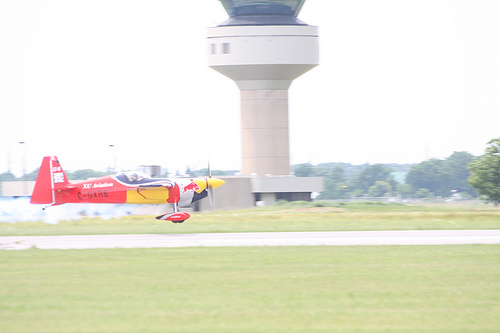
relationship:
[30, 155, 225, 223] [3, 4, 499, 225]
plane in air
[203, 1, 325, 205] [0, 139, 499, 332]
tower at airport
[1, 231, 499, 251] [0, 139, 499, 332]
runway at airport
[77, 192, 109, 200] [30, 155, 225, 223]
letters on plane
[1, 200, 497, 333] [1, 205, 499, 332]
grass on ground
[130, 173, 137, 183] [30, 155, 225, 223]
pilot in plane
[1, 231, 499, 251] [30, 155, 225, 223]
runway below plane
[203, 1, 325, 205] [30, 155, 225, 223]
tower behind plane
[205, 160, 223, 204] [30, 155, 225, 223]
propeller on plane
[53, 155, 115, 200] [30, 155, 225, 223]
decals on plane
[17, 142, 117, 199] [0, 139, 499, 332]
lights at airport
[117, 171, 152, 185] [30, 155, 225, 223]
cockpit of plane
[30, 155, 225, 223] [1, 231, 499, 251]
plane over runway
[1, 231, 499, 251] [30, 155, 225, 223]
runway under plane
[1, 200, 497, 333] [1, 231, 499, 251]
grass near runway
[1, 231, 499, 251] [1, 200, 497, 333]
runway near grass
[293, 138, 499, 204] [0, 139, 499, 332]
trees near airport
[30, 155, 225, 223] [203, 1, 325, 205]
plane near tower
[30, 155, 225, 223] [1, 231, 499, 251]
plane above runway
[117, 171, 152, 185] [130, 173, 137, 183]
cockpit for pilot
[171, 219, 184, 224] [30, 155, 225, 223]
wheels of plane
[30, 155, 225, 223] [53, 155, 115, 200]
plane has decals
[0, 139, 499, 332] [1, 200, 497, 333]
airport has grass